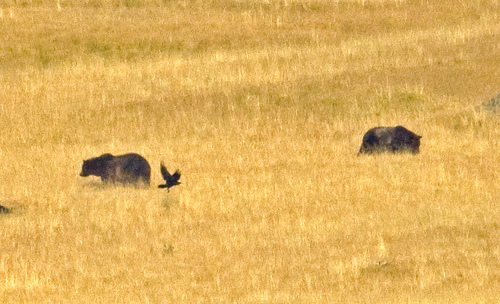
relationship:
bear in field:
[80, 152, 150, 184] [1, 0, 498, 302]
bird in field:
[155, 159, 183, 193] [1, 0, 498, 302]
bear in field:
[78, 152, 150, 188] [244, 168, 451, 268]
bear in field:
[78, 152, 150, 188] [1, 0, 498, 302]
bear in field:
[354, 125, 420, 156] [1, 0, 498, 302]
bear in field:
[80, 152, 150, 184] [40, 24, 327, 146]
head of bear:
[79, 156, 94, 177] [53, 112, 174, 207]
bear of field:
[78, 152, 150, 188] [1, 0, 498, 302]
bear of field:
[354, 125, 420, 156] [1, 0, 498, 302]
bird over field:
[152, 165, 201, 195] [143, 190, 493, 297]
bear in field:
[360, 125, 420, 153] [1, 0, 498, 302]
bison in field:
[77, 153, 152, 186] [1, 0, 498, 302]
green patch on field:
[368, 90, 425, 115] [1, 0, 498, 302]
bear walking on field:
[78, 152, 150, 188] [1, 0, 498, 302]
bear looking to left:
[78, 152, 150, 188] [332, 118, 498, 246]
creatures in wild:
[36, 96, 442, 219] [2, 68, 498, 304]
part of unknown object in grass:
[162, 216, 409, 267] [464, 94, 498, 126]